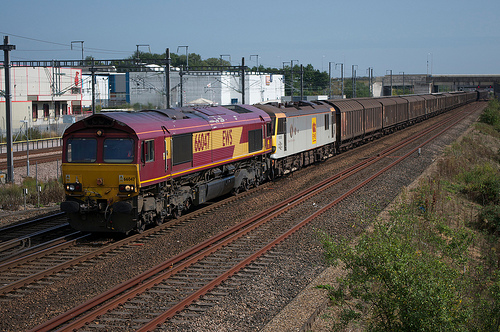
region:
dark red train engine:
[56, 108, 269, 230]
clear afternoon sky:
[271, 4, 496, 59]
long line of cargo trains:
[334, 79, 471, 159]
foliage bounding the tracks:
[284, 199, 496, 314]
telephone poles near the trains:
[0, 32, 27, 187]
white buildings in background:
[129, 73, 291, 106]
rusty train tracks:
[34, 99, 475, 317]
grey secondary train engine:
[263, 101, 339, 172]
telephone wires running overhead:
[9, 34, 188, 57]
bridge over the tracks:
[371, 69, 497, 92]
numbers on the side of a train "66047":
[193, 130, 211, 152]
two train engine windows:
[61, 134, 138, 163]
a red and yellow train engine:
[56, 98, 270, 237]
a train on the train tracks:
[58, 86, 480, 239]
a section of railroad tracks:
[59, 240, 226, 330]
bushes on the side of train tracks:
[328, 173, 497, 329]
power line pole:
[1, 32, 23, 187]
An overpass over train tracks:
[361, 68, 499, 88]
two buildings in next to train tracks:
[0, 62, 287, 102]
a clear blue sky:
[0, 0, 499, 60]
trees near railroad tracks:
[352, 134, 492, 322]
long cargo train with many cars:
[70, 76, 481, 219]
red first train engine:
[49, 106, 276, 238]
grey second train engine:
[265, 105, 344, 178]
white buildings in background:
[113, 67, 329, 118]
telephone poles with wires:
[1, 38, 30, 200]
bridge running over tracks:
[409, 71, 499, 104]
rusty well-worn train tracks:
[64, 106, 483, 329]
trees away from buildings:
[282, 62, 330, 96]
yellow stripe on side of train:
[152, 126, 262, 163]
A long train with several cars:
[60, 61, 478, 244]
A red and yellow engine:
[58, 104, 273, 235]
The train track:
[0, 99, 491, 328]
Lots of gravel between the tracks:
[0, 111, 442, 329]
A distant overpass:
[378, 73, 498, 87]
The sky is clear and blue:
[1, 1, 498, 78]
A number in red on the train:
[187, 131, 212, 151]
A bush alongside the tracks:
[321, 221, 481, 324]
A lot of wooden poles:
[0, 34, 432, 184]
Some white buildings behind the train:
[8, 54, 286, 121]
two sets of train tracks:
[0, 92, 487, 329]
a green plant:
[296, 201, 497, 330]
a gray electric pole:
[0, 33, 19, 190]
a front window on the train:
[101, 132, 134, 164]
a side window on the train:
[168, 128, 195, 167]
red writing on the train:
[192, 130, 212, 155]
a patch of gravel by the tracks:
[151, 98, 491, 330]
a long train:
[46, 85, 482, 247]